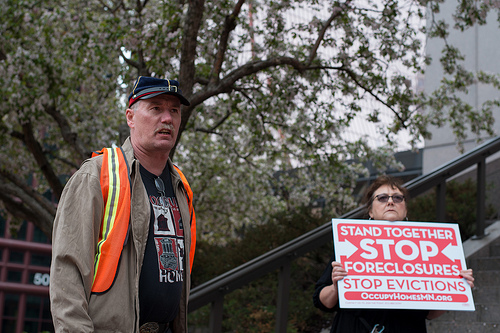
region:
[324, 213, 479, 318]
a red and white sign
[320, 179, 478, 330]
a woman holding a sign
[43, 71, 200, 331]
a man wearing a tan jacket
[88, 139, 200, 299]
a bright orange and yellow safety jacket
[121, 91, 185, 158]
a man's face with mustache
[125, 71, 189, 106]
a blue grey and red hat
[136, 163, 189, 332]
a black t-shirt with printing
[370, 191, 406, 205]
a pair of sunglasses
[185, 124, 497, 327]
a black metal railing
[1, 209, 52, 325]
red bars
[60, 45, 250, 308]
a man wearing orange vest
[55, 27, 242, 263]
man wearing hat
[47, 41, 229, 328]
a man wearing a hat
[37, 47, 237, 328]
a man wearing a jacket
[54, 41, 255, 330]
a man wearing a black shirt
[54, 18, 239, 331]
a man standing outside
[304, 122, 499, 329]
a women wearing glasses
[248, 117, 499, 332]
a women holding a sign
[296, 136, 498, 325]
a women protesting outside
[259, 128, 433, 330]
a women standing with a sign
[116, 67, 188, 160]
The man is wearing a cap.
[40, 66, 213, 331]
The man is wearuing a safety vest.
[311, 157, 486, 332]
The woman is holding a sign.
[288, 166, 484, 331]
The woman is wearing sunglasses.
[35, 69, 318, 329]
The man has a moustache.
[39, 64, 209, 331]
The man is wearing a tan shirt.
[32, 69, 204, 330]
The tan shirt is unbuttoned.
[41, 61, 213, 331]
Glasses are hooked over neck of shirt.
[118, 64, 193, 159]
The hat has a buckle.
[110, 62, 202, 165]
The cap is red, white and blue.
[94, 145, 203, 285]
The orange vest the man is wearing.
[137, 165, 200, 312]
The black t-shirt the man is wearing.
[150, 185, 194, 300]
The design on the man's shirt.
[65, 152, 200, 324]
The brown shirt the man is wearing.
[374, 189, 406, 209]
The glasses the lady is wearing.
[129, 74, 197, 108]
The hat the man is wearing.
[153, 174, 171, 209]
The glasses hanging on the man's shirt.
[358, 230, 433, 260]
The word Stop with arrows on both sides on the sign the lady is holding.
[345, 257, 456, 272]
The word Foreclosures on the sign the lady is holding.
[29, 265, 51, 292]
The number 50 on the building behind the man.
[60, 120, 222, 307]
an orange traffic vest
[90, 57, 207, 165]
a man wearing a black hat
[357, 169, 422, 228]
a woman wearing sunglasses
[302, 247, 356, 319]
a womans hand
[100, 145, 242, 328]
a man wearing a black shirt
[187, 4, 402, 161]
a large brown tree branch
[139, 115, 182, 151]
the man has a moustache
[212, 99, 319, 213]
green tree leaves